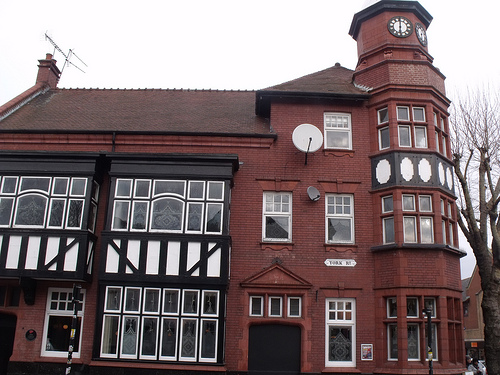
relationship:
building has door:
[4, 5, 470, 375] [250, 322, 301, 374]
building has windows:
[4, 5, 470, 375] [101, 284, 222, 361]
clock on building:
[389, 13, 409, 39] [4, 5, 470, 375]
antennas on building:
[42, 31, 94, 88] [4, 5, 470, 375]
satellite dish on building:
[291, 120, 322, 166] [4, 5, 470, 375]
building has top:
[4, 5, 470, 375] [2, 11, 453, 157]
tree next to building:
[450, 91, 500, 370] [4, 5, 470, 375]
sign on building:
[324, 257, 360, 271] [4, 5, 470, 375]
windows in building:
[260, 188, 355, 243] [4, 5, 470, 375]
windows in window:
[116, 180, 220, 233] [105, 150, 238, 279]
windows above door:
[248, 292, 302, 319] [250, 322, 301, 374]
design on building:
[372, 149, 458, 189] [4, 5, 470, 375]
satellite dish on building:
[306, 185, 322, 202] [4, 5, 470, 375]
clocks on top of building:
[388, 16, 428, 42] [4, 5, 470, 375]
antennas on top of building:
[42, 31, 94, 88] [4, 5, 470, 375]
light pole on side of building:
[61, 279, 82, 371] [4, 5, 470, 375]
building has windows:
[4, 5, 470, 375] [116, 180, 220, 233]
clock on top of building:
[389, 13, 409, 39] [4, 5, 470, 375]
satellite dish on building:
[305, 183, 323, 206] [4, 5, 470, 375]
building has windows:
[4, 5, 470, 375] [248, 292, 302, 319]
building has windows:
[4, 5, 470, 375] [260, 188, 355, 243]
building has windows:
[4, 5, 470, 375] [374, 101, 447, 153]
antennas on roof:
[42, 31, 94, 88] [10, 57, 363, 138]